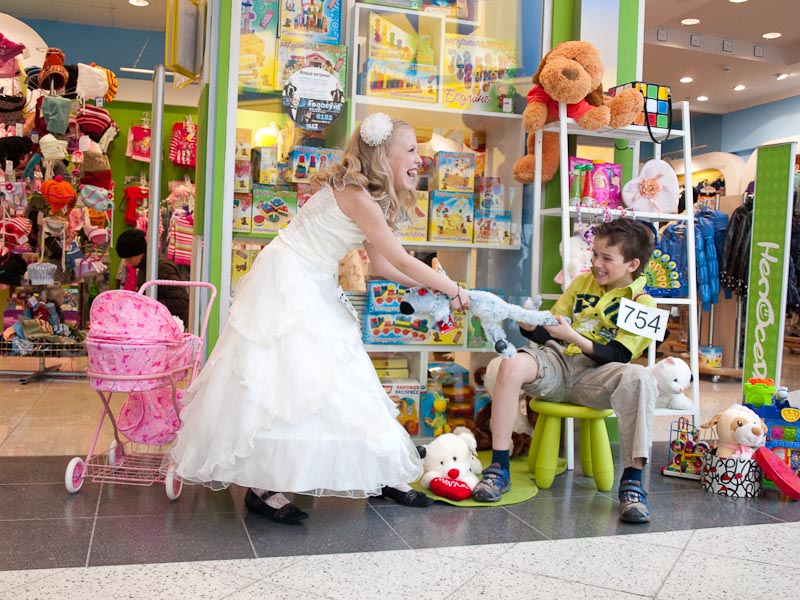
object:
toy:
[620, 75, 673, 128]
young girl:
[150, 169, 432, 515]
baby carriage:
[62, 270, 220, 502]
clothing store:
[2, 0, 188, 378]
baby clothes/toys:
[1, 3, 799, 501]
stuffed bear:
[511, 34, 644, 186]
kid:
[465, 205, 663, 516]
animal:
[458, 263, 580, 361]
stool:
[521, 396, 622, 488]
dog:
[516, 40, 642, 186]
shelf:
[530, 105, 694, 229]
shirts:
[123, 121, 165, 164]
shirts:
[166, 117, 198, 170]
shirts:
[120, 178, 155, 227]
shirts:
[160, 180, 206, 271]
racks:
[117, 54, 183, 294]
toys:
[358, 11, 437, 104]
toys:
[430, 138, 478, 192]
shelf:
[341, 4, 542, 256]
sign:
[737, 138, 800, 400]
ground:
[604, 376, 794, 597]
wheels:
[62, 444, 90, 494]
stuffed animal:
[414, 424, 483, 502]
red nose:
[442, 466, 460, 484]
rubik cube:
[615, 83, 667, 128]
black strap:
[635, 82, 683, 144]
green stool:
[521, 389, 620, 496]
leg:
[585, 421, 623, 494]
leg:
[529, 414, 566, 492]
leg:
[521, 418, 541, 477]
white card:
[618, 296, 670, 342]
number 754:
[622, 303, 663, 335]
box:
[618, 157, 688, 218]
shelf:
[533, 102, 691, 219]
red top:
[752, 440, 800, 499]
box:
[702, 452, 757, 496]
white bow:
[359, 112, 393, 146]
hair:
[295, 110, 432, 209]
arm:
[355, 198, 473, 310]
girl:
[156, 112, 433, 531]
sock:
[494, 445, 511, 461]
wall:
[65, 3, 194, 270]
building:
[0, 2, 785, 590]